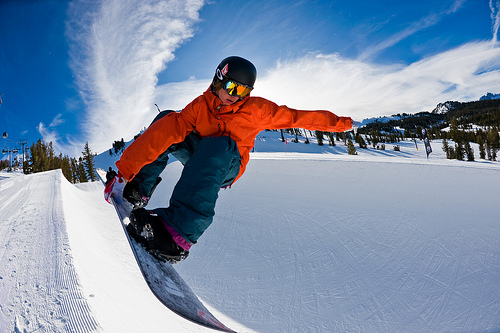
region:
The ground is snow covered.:
[312, 192, 460, 307]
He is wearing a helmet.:
[199, 56, 281, 120]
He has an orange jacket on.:
[127, 65, 339, 183]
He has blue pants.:
[105, 75, 232, 263]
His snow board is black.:
[100, 191, 200, 326]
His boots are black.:
[110, 169, 211, 281]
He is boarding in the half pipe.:
[72, 39, 494, 310]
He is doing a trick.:
[23, 115, 497, 252]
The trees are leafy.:
[15, 131, 112, 181]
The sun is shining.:
[55, 23, 453, 320]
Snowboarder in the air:
[72, 51, 364, 332]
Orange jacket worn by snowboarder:
[109, 71, 383, 211]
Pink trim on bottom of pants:
[157, 222, 197, 255]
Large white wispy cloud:
[55, 0, 497, 142]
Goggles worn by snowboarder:
[213, 67, 261, 100]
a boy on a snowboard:
[77, 48, 338, 332]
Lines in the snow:
[48, 201, 94, 332]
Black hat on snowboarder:
[201, 49, 261, 114]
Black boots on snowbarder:
[129, 210, 197, 275]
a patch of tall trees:
[23, 131, 108, 203]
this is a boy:
[137, 61, 283, 236]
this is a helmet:
[226, 51, 258, 83]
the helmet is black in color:
[230, 53, 252, 68]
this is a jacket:
[236, 114, 271, 143]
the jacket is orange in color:
[241, 108, 264, 132]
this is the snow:
[304, 198, 436, 267]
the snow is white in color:
[303, 152, 431, 304]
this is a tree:
[436, 116, 470, 165]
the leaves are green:
[461, 143, 474, 162]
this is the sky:
[12, 78, 66, 113]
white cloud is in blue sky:
[54, 1, 203, 90]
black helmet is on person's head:
[200, 52, 255, 109]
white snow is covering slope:
[278, 163, 488, 330]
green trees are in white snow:
[437, 127, 499, 171]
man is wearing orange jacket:
[103, 88, 363, 173]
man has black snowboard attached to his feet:
[90, 151, 239, 332]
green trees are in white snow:
[19, 133, 98, 194]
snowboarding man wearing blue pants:
[135, 107, 247, 246]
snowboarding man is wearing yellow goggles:
[217, 76, 253, 98]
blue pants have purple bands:
[130, 139, 220, 251]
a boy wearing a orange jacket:
[110, 62, 355, 196]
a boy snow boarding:
[95, 49, 367, 309]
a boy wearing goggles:
[188, 57, 276, 123]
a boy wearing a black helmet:
[182, 59, 278, 115]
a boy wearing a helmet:
[201, 59, 288, 121]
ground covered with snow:
[287, 170, 474, 315]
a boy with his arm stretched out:
[168, 69, 403, 167]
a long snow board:
[91, 178, 295, 331]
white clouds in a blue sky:
[293, 35, 460, 112]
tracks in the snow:
[291, 217, 471, 327]